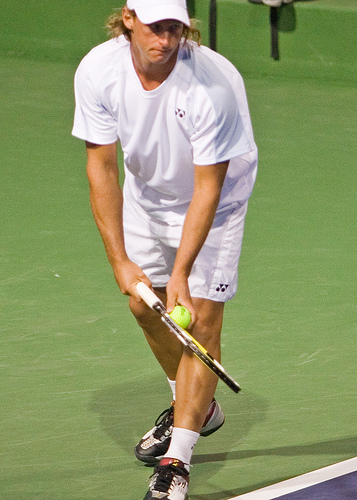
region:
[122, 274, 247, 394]
Tennis ball resting on tennis racket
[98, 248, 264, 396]
Tennis racket in man's hand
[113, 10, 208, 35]
White hat on man's head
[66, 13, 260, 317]
White tennis uniform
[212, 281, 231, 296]
Brand logo on shorts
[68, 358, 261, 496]
Shadow on tennis court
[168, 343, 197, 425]
Tight calf muscle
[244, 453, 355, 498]
Tennis court boundary lin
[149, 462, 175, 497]
Black shoe laces on tennis shoes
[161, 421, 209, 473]
White socks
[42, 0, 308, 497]
a tennis player preparing to serve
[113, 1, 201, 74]
a man wearing a cap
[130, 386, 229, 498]
the shoes of a tennis player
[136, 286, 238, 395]
the racket of a tennis player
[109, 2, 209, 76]
a man with blonde hair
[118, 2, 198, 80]
the head of a man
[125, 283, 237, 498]
the legs of a man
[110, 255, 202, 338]
the hands of a man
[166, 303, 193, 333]
a yellow tennis ball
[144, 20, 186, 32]
the eyes of a man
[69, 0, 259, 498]
tennis player about to serve the ball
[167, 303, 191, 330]
the green tennis ball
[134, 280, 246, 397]
the tennis racket and ball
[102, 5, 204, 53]
blonde hair flying out from under hat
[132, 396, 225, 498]
sneakers on tennis player's feet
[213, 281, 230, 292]
black logo on white shorts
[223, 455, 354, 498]
part of white boundary line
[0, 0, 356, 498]
a green court and wall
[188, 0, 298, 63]
things hanging over side of wall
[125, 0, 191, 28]
plain white hat on man's head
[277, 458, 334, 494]
a white line on a tennis court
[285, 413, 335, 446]
green surface on a tennis court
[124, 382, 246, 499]
a tennis player wearing black and white shoes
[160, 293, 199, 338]
a tennis ball in a players hand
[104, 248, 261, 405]
a player holding a tennis racket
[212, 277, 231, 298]
a logo on white shorts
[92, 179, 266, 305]
a player wearing white shorts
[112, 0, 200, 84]
a player wearing a white hat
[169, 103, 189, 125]
a logo on a tennis shirt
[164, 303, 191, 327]
a green tennis ball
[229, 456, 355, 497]
a white line on a tennis court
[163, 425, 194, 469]
a white sock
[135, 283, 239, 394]
a white, black, and yellow tennis sock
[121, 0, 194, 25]
a white colored cap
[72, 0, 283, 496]
a man wearing a white t-shirt and white shorts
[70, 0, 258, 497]
a man with long hair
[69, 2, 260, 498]
a man holding a tennis racket and tennis racket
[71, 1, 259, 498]
a man wearing white socks and black and white shoes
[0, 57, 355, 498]
a green tennis court